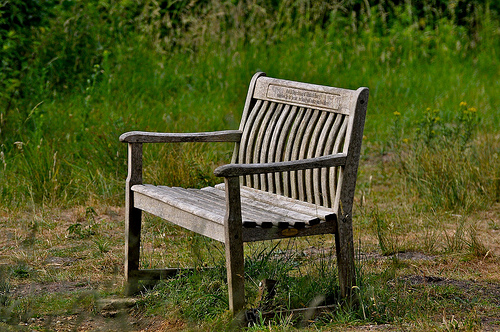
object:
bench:
[117, 71, 371, 324]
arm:
[214, 153, 347, 177]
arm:
[118, 130, 242, 144]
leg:
[124, 207, 142, 282]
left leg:
[226, 241, 246, 329]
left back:
[299, 95, 368, 207]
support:
[128, 179, 274, 245]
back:
[239, 71, 370, 154]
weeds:
[161, 272, 494, 325]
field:
[40, 31, 233, 125]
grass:
[400, 70, 500, 218]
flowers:
[393, 110, 401, 115]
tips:
[187, 0, 326, 24]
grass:
[120, 10, 487, 71]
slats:
[258, 108, 267, 164]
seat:
[130, 182, 338, 244]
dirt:
[53, 293, 204, 332]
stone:
[96, 299, 136, 314]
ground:
[0, 243, 185, 332]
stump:
[259, 306, 327, 319]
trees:
[146, 2, 465, 54]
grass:
[171, 257, 332, 314]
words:
[273, 85, 340, 107]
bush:
[409, 98, 497, 173]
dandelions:
[392, 101, 488, 119]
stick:
[254, 297, 336, 319]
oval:
[281, 228, 299, 236]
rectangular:
[265, 84, 342, 110]